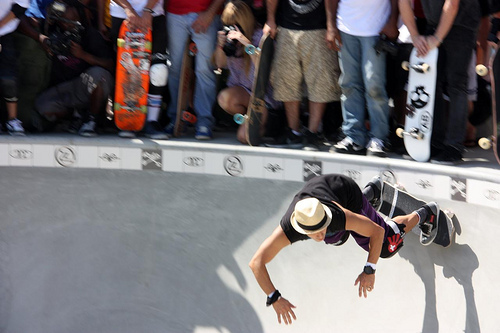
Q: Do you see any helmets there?
A: No, there are no helmets.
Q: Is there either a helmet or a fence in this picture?
A: No, there are no helmets or fences.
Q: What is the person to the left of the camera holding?
A: The person is holding the skateboard.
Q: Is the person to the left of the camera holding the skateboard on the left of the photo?
A: Yes, the person is holding the skateboard.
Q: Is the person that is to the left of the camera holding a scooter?
A: No, the person is holding the skateboard.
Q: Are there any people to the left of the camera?
A: Yes, there is a person to the left of the camera.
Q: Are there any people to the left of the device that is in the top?
A: Yes, there is a person to the left of the camera.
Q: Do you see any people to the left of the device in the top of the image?
A: Yes, there is a person to the left of the camera.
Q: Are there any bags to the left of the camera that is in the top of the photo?
A: No, there is a person to the left of the camera.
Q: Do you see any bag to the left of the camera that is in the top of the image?
A: No, there is a person to the left of the camera.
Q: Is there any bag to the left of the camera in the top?
A: No, there is a person to the left of the camera.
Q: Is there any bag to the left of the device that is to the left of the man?
A: No, there is a person to the left of the camera.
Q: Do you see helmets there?
A: No, there are no helmets.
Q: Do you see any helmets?
A: No, there are no helmets.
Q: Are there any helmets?
A: No, there are no helmets.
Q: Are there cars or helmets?
A: No, there are no helmets or cars.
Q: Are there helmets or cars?
A: No, there are no helmets or cars.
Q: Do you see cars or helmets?
A: No, there are no helmets or cars.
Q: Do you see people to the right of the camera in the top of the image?
A: Yes, there is a person to the right of the camera.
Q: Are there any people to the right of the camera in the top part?
A: Yes, there is a person to the right of the camera.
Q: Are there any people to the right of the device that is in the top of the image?
A: Yes, there is a person to the right of the camera.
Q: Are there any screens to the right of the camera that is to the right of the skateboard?
A: No, there is a person to the right of the camera.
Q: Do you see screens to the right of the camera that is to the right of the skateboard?
A: No, there is a person to the right of the camera.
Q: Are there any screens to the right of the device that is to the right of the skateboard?
A: No, there is a person to the right of the camera.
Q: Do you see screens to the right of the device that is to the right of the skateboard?
A: No, there is a person to the right of the camera.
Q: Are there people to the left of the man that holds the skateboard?
A: Yes, there is a person to the left of the man.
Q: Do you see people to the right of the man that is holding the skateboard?
A: No, the person is to the left of the man.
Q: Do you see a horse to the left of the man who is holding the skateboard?
A: No, there is a person to the left of the man.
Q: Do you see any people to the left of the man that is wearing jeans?
A: Yes, there is a person to the left of the man.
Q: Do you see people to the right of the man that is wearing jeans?
A: No, the person is to the left of the man.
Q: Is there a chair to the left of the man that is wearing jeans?
A: No, there is a person to the left of the man.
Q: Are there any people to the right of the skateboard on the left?
A: Yes, there is a person to the right of the skateboard.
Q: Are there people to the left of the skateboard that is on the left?
A: No, the person is to the right of the skateboard.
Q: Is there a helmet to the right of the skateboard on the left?
A: No, there is a person to the right of the skateboard.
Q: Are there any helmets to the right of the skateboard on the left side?
A: No, there is a person to the right of the skateboard.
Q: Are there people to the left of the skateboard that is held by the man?
A: Yes, there is a person to the left of the skateboard.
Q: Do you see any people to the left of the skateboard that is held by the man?
A: Yes, there is a person to the left of the skateboard.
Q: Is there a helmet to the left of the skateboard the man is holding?
A: No, there is a person to the left of the skateboard.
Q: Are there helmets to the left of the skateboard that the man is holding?
A: No, there is a person to the left of the skateboard.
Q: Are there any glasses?
A: No, there are no glasses.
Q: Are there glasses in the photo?
A: No, there are no glasses.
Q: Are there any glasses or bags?
A: No, there are no glasses or bags.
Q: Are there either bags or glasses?
A: No, there are no glasses or bags.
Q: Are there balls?
A: No, there are no balls.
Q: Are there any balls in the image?
A: No, there are no balls.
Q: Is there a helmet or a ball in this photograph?
A: No, there are no balls or helmets.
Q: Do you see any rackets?
A: No, there are no rackets.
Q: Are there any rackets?
A: No, there are no rackets.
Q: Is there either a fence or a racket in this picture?
A: No, there are no rackets or fences.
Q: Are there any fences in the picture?
A: No, there are no fences.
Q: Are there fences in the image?
A: No, there are no fences.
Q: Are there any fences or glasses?
A: No, there are no fences or glasses.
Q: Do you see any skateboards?
A: Yes, there is a skateboard.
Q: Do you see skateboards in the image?
A: Yes, there is a skateboard.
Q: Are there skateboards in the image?
A: Yes, there is a skateboard.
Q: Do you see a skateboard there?
A: Yes, there is a skateboard.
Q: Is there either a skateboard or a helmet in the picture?
A: Yes, there is a skateboard.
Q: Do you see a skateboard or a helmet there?
A: Yes, there is a skateboard.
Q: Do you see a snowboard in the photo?
A: No, there are no snowboards.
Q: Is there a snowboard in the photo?
A: No, there are no snowboards.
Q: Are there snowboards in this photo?
A: No, there are no snowboards.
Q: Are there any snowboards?
A: No, there are no snowboards.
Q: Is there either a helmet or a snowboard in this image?
A: No, there are no snowboards or helmets.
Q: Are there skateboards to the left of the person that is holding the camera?
A: Yes, there is a skateboard to the left of the person.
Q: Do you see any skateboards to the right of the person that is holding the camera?
A: No, the skateboard is to the left of the person.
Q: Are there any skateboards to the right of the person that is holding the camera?
A: No, the skateboard is to the left of the person.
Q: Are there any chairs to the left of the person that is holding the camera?
A: No, there is a skateboard to the left of the person.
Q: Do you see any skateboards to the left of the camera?
A: Yes, there is a skateboard to the left of the camera.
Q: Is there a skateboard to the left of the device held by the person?
A: Yes, there is a skateboard to the left of the camera.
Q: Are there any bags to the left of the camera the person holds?
A: No, there is a skateboard to the left of the camera.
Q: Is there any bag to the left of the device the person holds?
A: No, there is a skateboard to the left of the camera.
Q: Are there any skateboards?
A: Yes, there is a skateboard.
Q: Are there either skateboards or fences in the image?
A: Yes, there is a skateboard.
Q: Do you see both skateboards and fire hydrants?
A: No, there is a skateboard but no fire hydrants.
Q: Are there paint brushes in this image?
A: No, there are no paint brushes.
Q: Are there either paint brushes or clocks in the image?
A: No, there are no paint brushes or clocks.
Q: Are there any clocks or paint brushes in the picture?
A: No, there are no paint brushes or clocks.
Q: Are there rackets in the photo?
A: No, there are no rackets.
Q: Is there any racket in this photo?
A: No, there are no rackets.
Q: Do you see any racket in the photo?
A: No, there are no rackets.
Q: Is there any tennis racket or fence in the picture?
A: No, there are no rackets or fences.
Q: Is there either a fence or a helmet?
A: No, there are no helmets or fences.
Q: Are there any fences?
A: No, there are no fences.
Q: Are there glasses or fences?
A: No, there are no fences or glasses.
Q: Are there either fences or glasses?
A: No, there are no fences or glasses.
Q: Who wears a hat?
A: The man wears a hat.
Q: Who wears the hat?
A: The man wears a hat.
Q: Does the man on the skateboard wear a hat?
A: Yes, the man wears a hat.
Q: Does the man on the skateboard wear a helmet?
A: No, the man wears a hat.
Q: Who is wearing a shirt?
A: The man is wearing a shirt.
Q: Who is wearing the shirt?
A: The man is wearing a shirt.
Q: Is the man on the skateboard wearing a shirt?
A: Yes, the man is wearing a shirt.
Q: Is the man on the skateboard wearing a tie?
A: No, the man is wearing a shirt.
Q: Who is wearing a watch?
A: The man is wearing a watch.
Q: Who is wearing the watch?
A: The man is wearing a watch.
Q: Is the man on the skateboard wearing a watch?
A: Yes, the man is wearing a watch.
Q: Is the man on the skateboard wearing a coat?
A: No, the man is wearing a watch.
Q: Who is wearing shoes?
A: The man is wearing shoes.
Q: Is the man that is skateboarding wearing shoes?
A: Yes, the man is wearing shoes.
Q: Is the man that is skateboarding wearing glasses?
A: No, the man is wearing shoes.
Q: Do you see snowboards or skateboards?
A: Yes, there is a skateboard.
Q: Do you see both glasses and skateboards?
A: No, there is a skateboard but no glasses.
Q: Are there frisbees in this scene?
A: No, there are no frisbees.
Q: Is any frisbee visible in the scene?
A: No, there are no frisbees.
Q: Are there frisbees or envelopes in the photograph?
A: No, there are no frisbees or envelopes.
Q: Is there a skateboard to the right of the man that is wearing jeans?
A: Yes, there is a skateboard to the right of the man.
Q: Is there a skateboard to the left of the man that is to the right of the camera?
A: No, the skateboard is to the right of the man.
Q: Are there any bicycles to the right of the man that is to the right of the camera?
A: No, there is a skateboard to the right of the man.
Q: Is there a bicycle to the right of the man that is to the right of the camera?
A: No, there is a skateboard to the right of the man.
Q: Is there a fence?
A: No, there are no fences.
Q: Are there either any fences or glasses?
A: No, there are no fences or glasses.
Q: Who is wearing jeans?
A: The man is wearing jeans.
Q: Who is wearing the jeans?
A: The man is wearing jeans.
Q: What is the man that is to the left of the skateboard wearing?
A: The man is wearing jeans.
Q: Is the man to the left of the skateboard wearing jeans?
A: Yes, the man is wearing jeans.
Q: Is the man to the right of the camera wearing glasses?
A: No, the man is wearing jeans.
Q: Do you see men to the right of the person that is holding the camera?
A: Yes, there is a man to the right of the person.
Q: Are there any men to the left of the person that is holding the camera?
A: No, the man is to the right of the person.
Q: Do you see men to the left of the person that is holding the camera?
A: No, the man is to the right of the person.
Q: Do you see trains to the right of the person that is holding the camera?
A: No, there is a man to the right of the person.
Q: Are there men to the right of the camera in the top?
A: Yes, there is a man to the right of the camera.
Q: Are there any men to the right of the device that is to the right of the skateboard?
A: Yes, there is a man to the right of the camera.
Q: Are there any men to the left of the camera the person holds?
A: No, the man is to the right of the camera.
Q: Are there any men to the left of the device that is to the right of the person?
A: No, the man is to the right of the camera.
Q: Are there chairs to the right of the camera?
A: No, there is a man to the right of the camera.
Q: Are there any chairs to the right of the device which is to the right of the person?
A: No, there is a man to the right of the camera.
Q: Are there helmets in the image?
A: No, there are no helmets.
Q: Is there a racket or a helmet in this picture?
A: No, there are no helmets or rackets.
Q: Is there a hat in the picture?
A: Yes, there is a hat.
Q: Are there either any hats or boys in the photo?
A: Yes, there is a hat.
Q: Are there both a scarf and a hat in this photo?
A: No, there is a hat but no scarves.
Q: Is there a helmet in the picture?
A: No, there are no helmets.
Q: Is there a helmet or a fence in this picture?
A: No, there are no helmets or fences.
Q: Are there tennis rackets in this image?
A: No, there are no tennis rackets.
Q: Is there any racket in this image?
A: No, there are no rackets.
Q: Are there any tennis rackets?
A: No, there are no tennis rackets.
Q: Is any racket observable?
A: No, there are no rackets.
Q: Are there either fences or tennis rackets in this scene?
A: No, there are no tennis rackets or fences.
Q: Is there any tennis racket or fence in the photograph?
A: No, there are no rackets or fences.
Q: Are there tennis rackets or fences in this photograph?
A: No, there are no tennis rackets or fences.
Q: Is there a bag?
A: No, there are no bags.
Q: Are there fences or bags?
A: No, there are no bags or fences.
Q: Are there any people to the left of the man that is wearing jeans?
A: Yes, there is a person to the left of the man.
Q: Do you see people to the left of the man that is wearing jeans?
A: Yes, there is a person to the left of the man.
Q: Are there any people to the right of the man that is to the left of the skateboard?
A: No, the person is to the left of the man.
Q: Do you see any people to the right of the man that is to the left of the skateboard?
A: No, the person is to the left of the man.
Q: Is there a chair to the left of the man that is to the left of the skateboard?
A: No, there is a person to the left of the man.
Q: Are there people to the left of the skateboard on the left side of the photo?
A: No, the person is to the right of the skateboard.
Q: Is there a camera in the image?
A: Yes, there is a camera.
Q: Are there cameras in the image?
A: Yes, there is a camera.